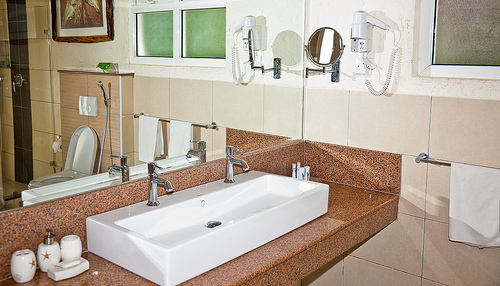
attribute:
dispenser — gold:
[38, 228, 62, 273]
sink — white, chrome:
[87, 171, 330, 286]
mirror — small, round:
[309, 27, 342, 66]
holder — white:
[11, 248, 37, 284]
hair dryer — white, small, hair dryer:
[353, 7, 408, 97]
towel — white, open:
[450, 161, 499, 246]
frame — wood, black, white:
[52, 1, 114, 44]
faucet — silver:
[226, 147, 248, 183]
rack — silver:
[416, 154, 449, 168]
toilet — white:
[29, 124, 99, 189]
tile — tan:
[303, 89, 348, 145]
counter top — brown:
[0, 127, 403, 285]